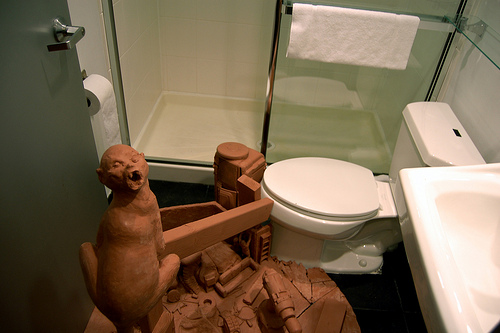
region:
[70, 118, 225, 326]
the monkey is facing the camera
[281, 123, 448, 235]
Toilet is white color.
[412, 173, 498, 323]
Sink is white color.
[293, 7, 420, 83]
Towel is in hanger.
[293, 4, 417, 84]
Towel is white color.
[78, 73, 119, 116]
Tissue paper is white color.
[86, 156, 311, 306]
Statue is brown color.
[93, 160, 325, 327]
Statue is kept in the toilet.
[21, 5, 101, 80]
Door handle is silver color.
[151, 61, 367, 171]
Bath room is white color.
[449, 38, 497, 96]
Wall is white color.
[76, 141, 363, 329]
There is a clay fixture depicting a monkey.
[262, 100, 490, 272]
There is a toilet to the right of the image.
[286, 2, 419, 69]
There is a towel on the rack.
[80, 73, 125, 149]
toilet paper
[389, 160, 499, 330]
The edge of a sink.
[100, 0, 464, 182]
Shower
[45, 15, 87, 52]
Doorknob.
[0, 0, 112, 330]
A grey door.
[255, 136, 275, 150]
A drain in the center of the shower.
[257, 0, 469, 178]
A glass door.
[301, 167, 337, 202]
top of a lid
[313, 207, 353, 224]
edge of a lid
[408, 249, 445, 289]
edge of a sink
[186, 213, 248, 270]
part of a statue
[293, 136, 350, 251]
part of a toilet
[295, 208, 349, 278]
side of a toilet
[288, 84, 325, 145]
part of a mirror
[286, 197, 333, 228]
part of a toilet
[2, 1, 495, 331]
a bathroom with a carving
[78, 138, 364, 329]
a reddish brown carving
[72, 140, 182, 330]
a strange cat creature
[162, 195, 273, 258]
a small wooden beam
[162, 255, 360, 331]
a hand crafted carving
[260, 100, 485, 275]
toilet in a bathroom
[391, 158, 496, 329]
part of a bathroom sink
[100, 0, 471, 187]
a shower in bathroom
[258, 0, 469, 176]
a shower door in bathroom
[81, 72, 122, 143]
roll of toilet paper